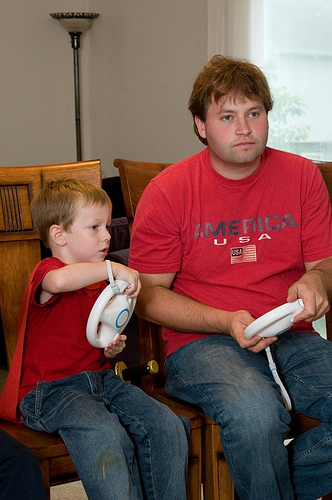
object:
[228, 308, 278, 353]
hands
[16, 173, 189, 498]
kid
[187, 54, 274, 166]
head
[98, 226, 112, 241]
nose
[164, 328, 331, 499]
blue jeans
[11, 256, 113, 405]
shirt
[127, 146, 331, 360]
shirt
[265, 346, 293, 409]
wire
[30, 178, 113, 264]
boyhead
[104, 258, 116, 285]
strap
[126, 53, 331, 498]
man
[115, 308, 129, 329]
circle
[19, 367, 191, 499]
jeans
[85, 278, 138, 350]
steering wheel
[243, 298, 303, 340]
steering wheel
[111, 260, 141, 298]
hands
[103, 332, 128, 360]
hands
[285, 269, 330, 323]
hands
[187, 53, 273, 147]
hair